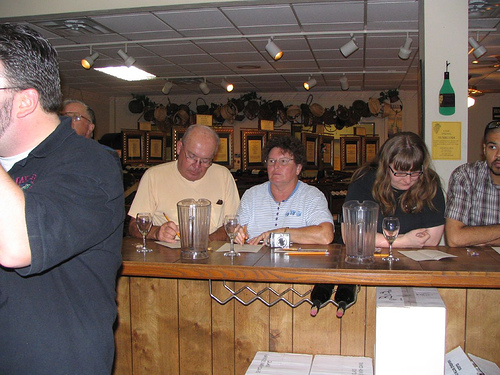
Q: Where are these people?
A: At a bar.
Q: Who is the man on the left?
A: The bartender.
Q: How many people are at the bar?
A: Five.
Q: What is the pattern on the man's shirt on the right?
A: Plaid.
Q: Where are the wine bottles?
A: Under the bar.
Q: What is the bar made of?
A: Wood.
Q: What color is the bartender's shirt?
A: Black.